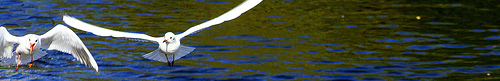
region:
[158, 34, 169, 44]
bird's beak is orange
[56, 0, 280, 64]
the bird is white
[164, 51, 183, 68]
bird's legs are brown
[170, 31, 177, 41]
bird's eye is black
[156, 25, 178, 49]
bird's head turned to left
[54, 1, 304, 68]
bird's wings extended out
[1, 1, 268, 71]
birds flying over water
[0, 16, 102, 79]
bird is further ahead then other bird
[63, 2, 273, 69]
bird is looking at other bird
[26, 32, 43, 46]
both bird's eyes visible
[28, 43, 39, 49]
Bird has orange beak.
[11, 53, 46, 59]
Bird has orange legs.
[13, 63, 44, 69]
Bird has orange feet.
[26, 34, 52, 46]
Bird has dark eyes.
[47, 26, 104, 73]
Bird has white wing.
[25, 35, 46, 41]
Bird has white head.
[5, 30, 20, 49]
Bird has white wing.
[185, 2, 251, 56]
Bird has white wing.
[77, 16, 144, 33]
Bird has white wing.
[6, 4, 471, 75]
2 white birds in flight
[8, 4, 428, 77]
2 birds soaring over calm water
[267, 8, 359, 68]
calm glassy water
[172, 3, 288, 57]
an extended white wing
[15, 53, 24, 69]
the orange foot of a water bird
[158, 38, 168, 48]
the black tipped beak of a sea bird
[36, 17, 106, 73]
a wing about to flap for loft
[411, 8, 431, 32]
flotsam in the water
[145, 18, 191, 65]
a bird looking to its right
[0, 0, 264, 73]
the birds are in motion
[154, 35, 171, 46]
the beak is orange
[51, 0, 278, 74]
the wings are wide open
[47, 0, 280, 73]
the bird is white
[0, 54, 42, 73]
the feet are orange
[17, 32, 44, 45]
the eyes are black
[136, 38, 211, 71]
the tail is fanned open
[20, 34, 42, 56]
the mouth is open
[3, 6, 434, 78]
a scene outside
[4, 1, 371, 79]
two white birds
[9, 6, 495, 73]
a blue pond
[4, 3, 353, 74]
some birds flying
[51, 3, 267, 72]
a bird with its wings out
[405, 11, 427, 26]
a leaf on the water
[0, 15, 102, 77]
a white bird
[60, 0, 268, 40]
outstretched wings of a bird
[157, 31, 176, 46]
turned head of a bird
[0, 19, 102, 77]
bird with orange legs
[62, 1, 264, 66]
A white bird flying with wings extended.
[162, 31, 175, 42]
White head on a bird with wings extended.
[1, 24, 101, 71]
White bird with orange legs and smaller wings.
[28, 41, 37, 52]
Orange beak that is opened.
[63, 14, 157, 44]
Long white wing over another bird.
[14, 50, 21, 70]
A bird's very orange right leg.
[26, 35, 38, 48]
White head on a bird with opened beak.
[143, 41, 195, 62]
White tail feathers on a larger winged bird.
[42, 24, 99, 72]
A white bird's left wing under a larger wing.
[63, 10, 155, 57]
wing of a seagull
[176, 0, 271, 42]
wing of a seagull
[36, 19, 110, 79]
wing of a seagull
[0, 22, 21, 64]
wing of a seagull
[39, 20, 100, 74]
wing of a seagull